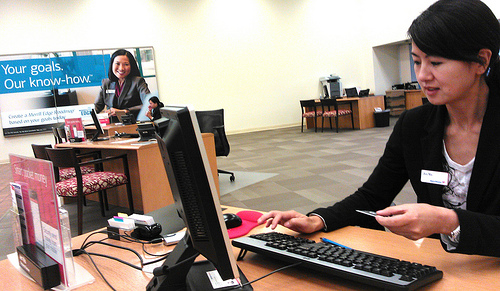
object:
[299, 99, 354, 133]
chairs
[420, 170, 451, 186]
name tag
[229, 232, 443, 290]
keyboard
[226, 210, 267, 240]
mousepad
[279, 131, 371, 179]
floor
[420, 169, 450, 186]
badge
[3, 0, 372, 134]
wall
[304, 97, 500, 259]
top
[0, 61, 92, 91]
lettering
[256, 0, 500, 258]
lady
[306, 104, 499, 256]
jacket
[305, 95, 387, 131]
desk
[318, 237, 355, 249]
pen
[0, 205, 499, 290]
desk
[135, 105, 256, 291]
computer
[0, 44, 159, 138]
sign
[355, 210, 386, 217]
credit card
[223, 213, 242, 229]
black mouse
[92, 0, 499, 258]
women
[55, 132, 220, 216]
desk